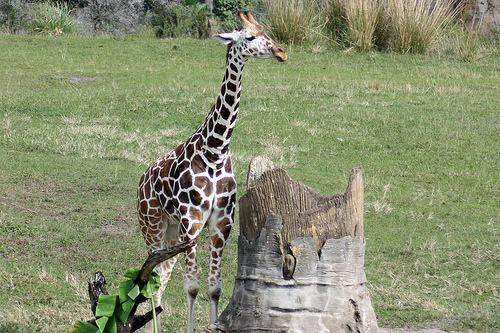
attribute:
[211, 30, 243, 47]
ear — white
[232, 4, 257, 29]
horn — giraffe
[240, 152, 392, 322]
stump — broken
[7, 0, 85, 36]
foliage — green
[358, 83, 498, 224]
grass — sparse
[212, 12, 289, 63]
head — giraffe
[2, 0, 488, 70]
shrubs — low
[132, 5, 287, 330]
giraffe — brown, standing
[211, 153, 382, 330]
tree stump — broken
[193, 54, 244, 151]
neck — long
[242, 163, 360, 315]
bark — peeling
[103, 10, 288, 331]
giraffe — standing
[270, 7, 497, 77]
foilage — thick, dry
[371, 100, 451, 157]
grass — brown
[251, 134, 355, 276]
stump — broken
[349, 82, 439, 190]
grass — dry, brown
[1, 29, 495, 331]
grass — green, bright, cut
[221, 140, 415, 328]
trunk — broken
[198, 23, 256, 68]
ear — white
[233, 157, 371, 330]
tree stump — old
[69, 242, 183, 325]
plant — withering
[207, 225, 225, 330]
leg — long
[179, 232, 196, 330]
leg — long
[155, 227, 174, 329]
leg — long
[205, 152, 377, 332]
stump — broken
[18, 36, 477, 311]
grass — high, growing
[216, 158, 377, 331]
stump — tree, broken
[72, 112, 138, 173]
grass — brown, dead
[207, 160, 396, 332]
tree stump — brown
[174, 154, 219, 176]
spots — dark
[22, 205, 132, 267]
grass — green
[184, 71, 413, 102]
spots — brown